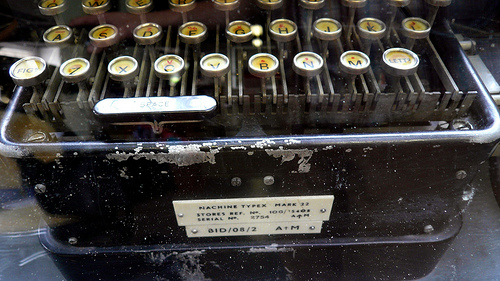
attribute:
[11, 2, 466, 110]
key — orange, silver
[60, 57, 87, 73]
key — silver, orange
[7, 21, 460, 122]
typewriter — silver, orange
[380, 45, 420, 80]
key — silver, orange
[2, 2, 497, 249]
typewriter — old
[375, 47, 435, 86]
key — orange, silver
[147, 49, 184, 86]
typewriter — old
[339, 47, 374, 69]
key — orange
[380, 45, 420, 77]
tin — small, plastic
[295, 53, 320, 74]
key — silver, orange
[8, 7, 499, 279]
typewriter — silver, orange, old, old fashioned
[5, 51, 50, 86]
key — silver, orange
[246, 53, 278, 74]
key — orange, silver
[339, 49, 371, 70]
key — silver, orange, old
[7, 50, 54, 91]
tin — small, plastic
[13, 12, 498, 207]
typewriter — silver, old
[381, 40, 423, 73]
key — silver, orange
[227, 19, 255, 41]
tin — small, plastic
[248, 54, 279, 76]
key — silver, orange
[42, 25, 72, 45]
key — silver, orange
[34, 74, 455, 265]
tin — plastic, small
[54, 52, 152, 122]
tin — small, plastic